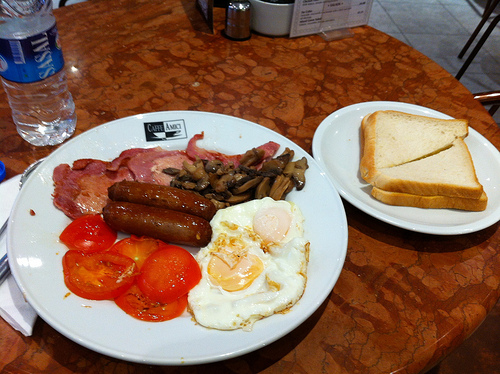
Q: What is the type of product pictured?
A: Food.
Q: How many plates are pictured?
A: Two.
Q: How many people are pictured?
A: None.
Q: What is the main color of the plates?
A: White.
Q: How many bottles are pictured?
A: One.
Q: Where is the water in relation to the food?
A: To the left.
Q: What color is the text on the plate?
A: Black.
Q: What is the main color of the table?
A: Brown.